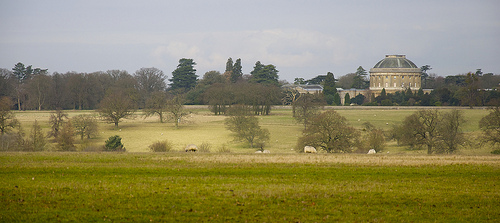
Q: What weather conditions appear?
A: It is cloudy.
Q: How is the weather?
A: It is cloudy.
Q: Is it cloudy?
A: Yes, it is cloudy.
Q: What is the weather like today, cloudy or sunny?
A: It is cloudy.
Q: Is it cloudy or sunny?
A: It is cloudy.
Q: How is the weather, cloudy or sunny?
A: It is cloudy.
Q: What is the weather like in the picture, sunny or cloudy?
A: It is cloudy.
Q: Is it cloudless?
A: No, it is cloudy.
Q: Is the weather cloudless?
A: No, it is cloudy.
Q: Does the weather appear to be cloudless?
A: No, it is cloudy.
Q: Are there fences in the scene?
A: No, there are no fences.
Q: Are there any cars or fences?
A: No, there are no fences or cars.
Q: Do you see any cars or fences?
A: No, there are no fences or cars.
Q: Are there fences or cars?
A: No, there are no fences or cars.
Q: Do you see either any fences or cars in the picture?
A: No, there are no fences or cars.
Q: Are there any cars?
A: No, there are no cars.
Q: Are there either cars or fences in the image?
A: No, there are no cars or fences.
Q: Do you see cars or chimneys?
A: No, there are no cars or chimneys.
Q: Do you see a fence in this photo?
A: No, there are no fences.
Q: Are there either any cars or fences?
A: No, there are no fences or cars.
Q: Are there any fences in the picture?
A: No, there are no fences.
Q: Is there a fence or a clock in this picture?
A: No, there are no fences or clocks.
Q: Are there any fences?
A: No, there are no fences.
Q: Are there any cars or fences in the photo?
A: No, there are no fences or cars.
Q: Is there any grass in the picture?
A: Yes, there is grass.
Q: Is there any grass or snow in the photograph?
A: Yes, there is grass.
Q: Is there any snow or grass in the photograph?
A: Yes, there is grass.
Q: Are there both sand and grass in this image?
A: No, there is grass but no sand.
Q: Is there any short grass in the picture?
A: Yes, there is short grass.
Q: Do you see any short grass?
A: Yes, there is short grass.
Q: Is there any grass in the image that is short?
A: Yes, there is grass that is short.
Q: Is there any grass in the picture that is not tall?
A: Yes, there is short grass.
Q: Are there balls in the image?
A: No, there are no balls.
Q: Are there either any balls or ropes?
A: No, there are no balls or ropes.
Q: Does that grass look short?
A: Yes, the grass is short.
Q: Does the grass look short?
A: Yes, the grass is short.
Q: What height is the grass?
A: The grass is short.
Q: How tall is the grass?
A: The grass is short.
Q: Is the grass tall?
A: No, the grass is short.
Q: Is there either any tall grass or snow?
A: No, there is grass but it is short.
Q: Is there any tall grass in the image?
A: No, there is grass but it is short.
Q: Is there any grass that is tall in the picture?
A: No, there is grass but it is short.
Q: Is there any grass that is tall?
A: No, there is grass but it is short.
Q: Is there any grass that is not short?
A: No, there is grass but it is short.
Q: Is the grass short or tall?
A: The grass is short.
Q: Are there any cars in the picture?
A: No, there are no cars.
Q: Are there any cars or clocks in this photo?
A: No, there are no cars or clocks.